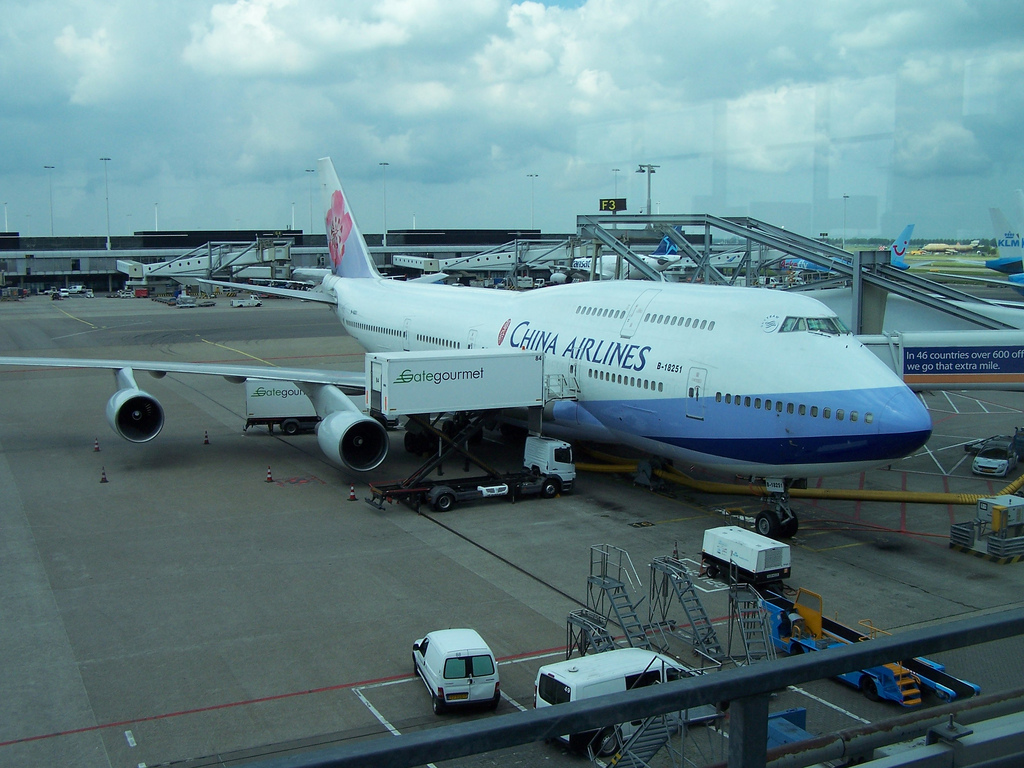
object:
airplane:
[0, 157, 1022, 493]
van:
[413, 629, 501, 716]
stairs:
[562, 544, 729, 666]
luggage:
[701, 526, 791, 586]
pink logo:
[325, 189, 355, 269]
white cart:
[364, 346, 547, 417]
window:
[588, 367, 665, 392]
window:
[822, 406, 831, 418]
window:
[715, 391, 721, 403]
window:
[755, 397, 761, 409]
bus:
[532, 647, 718, 757]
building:
[147, 608, 1021, 768]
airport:
[0, 154, 1021, 767]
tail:
[306, 156, 378, 280]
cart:
[362, 436, 575, 512]